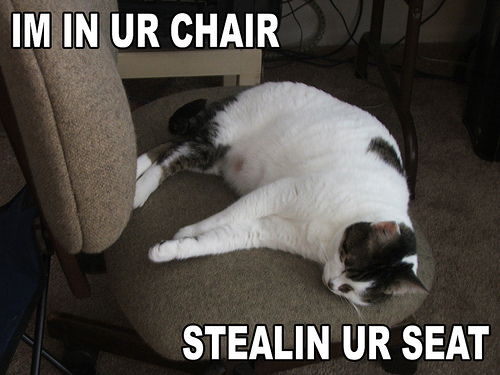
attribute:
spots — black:
[164, 93, 235, 171]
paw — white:
[146, 233, 179, 265]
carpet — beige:
[417, 96, 496, 373]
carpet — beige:
[278, 47, 398, 112]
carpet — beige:
[11, 277, 125, 374]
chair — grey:
[4, 1, 437, 373]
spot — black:
[356, 125, 426, 207]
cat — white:
[136, 66, 458, 338]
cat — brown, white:
[142, 69, 430, 283]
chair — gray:
[3, 17, 449, 361]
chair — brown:
[21, 36, 452, 350]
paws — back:
[145, 228, 187, 265]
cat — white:
[129, 72, 436, 309]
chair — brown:
[8, 32, 478, 328]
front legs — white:
[143, 195, 303, 266]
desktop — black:
[464, 2, 496, 169]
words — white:
[183, 324, 490, 361]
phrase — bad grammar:
[179, 315, 491, 366]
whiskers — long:
[347, 303, 371, 323]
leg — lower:
[134, 149, 151, 184]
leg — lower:
[134, 167, 167, 206]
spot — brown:
[358, 128, 404, 178]